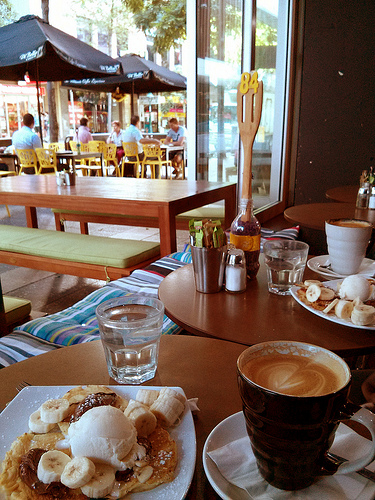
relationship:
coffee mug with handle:
[231, 342, 374, 486] [322, 405, 372, 478]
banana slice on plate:
[132, 407, 155, 433] [0, 384, 196, 498]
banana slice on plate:
[39, 395, 68, 420] [0, 384, 196, 498]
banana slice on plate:
[151, 401, 176, 427] [0, 384, 196, 498]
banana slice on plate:
[133, 390, 154, 401] [0, 384, 196, 498]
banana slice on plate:
[159, 387, 187, 405] [0, 384, 196, 498]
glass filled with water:
[90, 293, 169, 388] [98, 303, 158, 376]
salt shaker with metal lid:
[226, 248, 245, 294] [226, 248, 245, 268]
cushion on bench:
[34, 220, 145, 272] [20, 232, 132, 299]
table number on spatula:
[238, 72, 257, 95] [236, 70, 264, 223]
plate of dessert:
[2, 330, 252, 425] [2, 383, 190, 498]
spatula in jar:
[236, 70, 264, 223] [229, 198, 261, 277]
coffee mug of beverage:
[235, 338, 375, 492] [243, 352, 339, 394]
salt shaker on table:
[226, 248, 245, 294] [224, 268, 258, 328]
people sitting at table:
[65, 110, 193, 166] [139, 140, 186, 180]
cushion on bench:
[0, 224, 162, 270] [0, 221, 162, 284]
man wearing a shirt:
[13, 113, 67, 172] [9, 123, 43, 150]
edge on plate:
[187, 430, 196, 475] [0, 384, 196, 498]